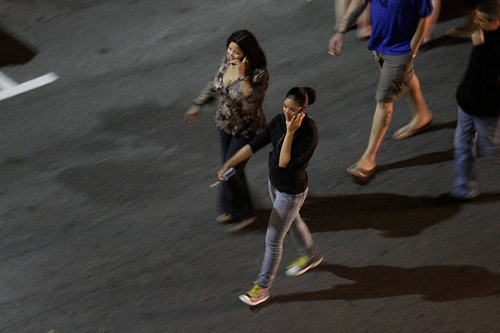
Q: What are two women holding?
A: Cell phones.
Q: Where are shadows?
A: On the ground.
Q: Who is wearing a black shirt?
A: Woman on right.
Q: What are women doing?
A: Talking on cell phone.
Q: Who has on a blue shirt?
A: One man.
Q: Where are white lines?
A: On the ground.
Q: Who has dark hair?
A: Two women.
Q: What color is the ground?
A: Gray.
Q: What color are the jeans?
A: Blue.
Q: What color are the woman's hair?
A: Black.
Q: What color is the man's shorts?
A: Gray.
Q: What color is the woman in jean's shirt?
A: Black.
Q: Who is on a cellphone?
A: The women.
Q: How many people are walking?
A: 4.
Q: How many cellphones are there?
A: 2.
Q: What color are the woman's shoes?
A: Green.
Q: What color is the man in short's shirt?
A: Blue.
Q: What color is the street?
A: Gray.